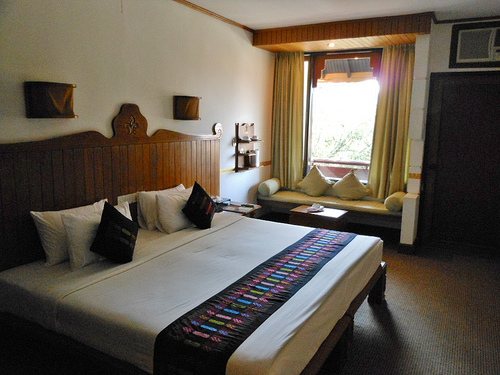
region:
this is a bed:
[162, 222, 305, 374]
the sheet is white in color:
[185, 235, 245, 276]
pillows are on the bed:
[35, 176, 216, 265]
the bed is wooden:
[103, 138, 158, 180]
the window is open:
[312, 77, 369, 159]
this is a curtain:
[375, 45, 410, 181]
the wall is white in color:
[127, 31, 225, 86]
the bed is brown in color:
[107, 133, 168, 180]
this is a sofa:
[301, 175, 388, 211]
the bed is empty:
[233, 229, 278, 272]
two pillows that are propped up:
[297, 164, 369, 201]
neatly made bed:
[6, 167, 400, 370]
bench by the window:
[263, 155, 411, 230]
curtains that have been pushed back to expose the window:
[273, 51, 407, 191]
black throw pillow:
[89, 201, 143, 263]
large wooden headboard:
[1, 104, 226, 265]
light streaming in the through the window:
[313, 79, 373, 164]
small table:
[290, 196, 348, 233]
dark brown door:
[416, 68, 496, 258]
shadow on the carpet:
[371, 300, 401, 347]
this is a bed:
[141, 220, 361, 315]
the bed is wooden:
[76, 152, 187, 169]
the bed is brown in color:
[103, 146, 177, 182]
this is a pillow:
[189, 184, 209, 221]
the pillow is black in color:
[189, 205, 205, 215]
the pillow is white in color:
[161, 192, 174, 214]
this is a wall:
[91, 8, 163, 77]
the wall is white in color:
[78, 30, 161, 74]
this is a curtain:
[285, 57, 304, 169]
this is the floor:
[398, 276, 457, 334]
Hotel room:
[8, 5, 483, 357]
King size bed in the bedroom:
[26, 105, 397, 363]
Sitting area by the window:
[186, 10, 478, 290]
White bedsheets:
[21, 155, 376, 367]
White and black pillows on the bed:
[12, 133, 419, 308]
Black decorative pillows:
[84, 186, 262, 255]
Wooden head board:
[3, 120, 326, 237]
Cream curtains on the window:
[222, 9, 425, 231]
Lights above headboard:
[21, 65, 291, 167]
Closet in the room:
[384, 50, 496, 280]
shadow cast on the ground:
[358, 315, 443, 358]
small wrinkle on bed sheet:
[286, 297, 332, 328]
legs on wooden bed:
[365, 255, 392, 303]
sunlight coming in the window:
[304, 54, 399, 167]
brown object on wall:
[167, 80, 212, 126]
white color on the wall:
[73, 17, 205, 73]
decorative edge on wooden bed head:
[103, 95, 153, 140]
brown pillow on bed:
[179, 173, 234, 246]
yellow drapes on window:
[273, 30, 422, 207]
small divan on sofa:
[258, 170, 303, 207]